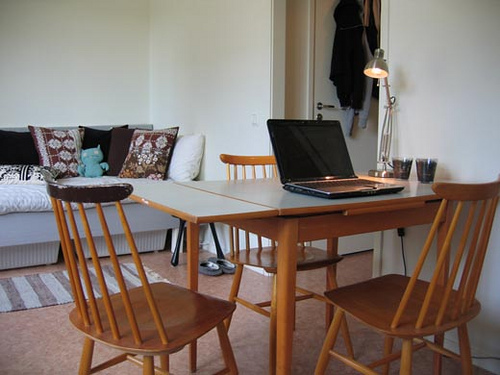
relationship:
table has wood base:
[127, 173, 454, 374] [187, 199, 453, 374]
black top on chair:
[45, 180, 133, 203] [46, 179, 237, 374]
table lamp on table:
[363, 49, 396, 177] [127, 173, 454, 374]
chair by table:
[46, 179, 237, 374] [127, 173, 454, 374]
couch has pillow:
[1, 123, 205, 270] [118, 151, 172, 180]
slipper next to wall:
[197, 255, 235, 275] [148, 0, 273, 278]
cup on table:
[415, 158, 438, 183] [127, 173, 454, 374]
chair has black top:
[46, 179, 237, 374] [45, 180, 133, 203]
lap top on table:
[267, 119, 405, 198] [127, 173, 454, 374]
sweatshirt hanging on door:
[329, 2, 366, 110] [315, 0, 380, 254]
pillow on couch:
[28, 126, 84, 177] [1, 123, 205, 270]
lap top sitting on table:
[267, 119, 405, 198] [127, 173, 454, 374]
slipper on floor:
[197, 255, 235, 275] [0, 247, 499, 374]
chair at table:
[46, 179, 237, 374] [127, 173, 454, 374]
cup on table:
[392, 157, 413, 180] [127, 173, 454, 374]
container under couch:
[0, 240, 60, 269] [1, 123, 205, 270]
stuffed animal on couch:
[77, 144, 109, 177] [1, 123, 205, 270]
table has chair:
[127, 173, 454, 374] [312, 173, 499, 374]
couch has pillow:
[1, 123, 205, 270] [28, 126, 84, 177]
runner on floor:
[0, 262, 172, 314] [0, 247, 499, 374]